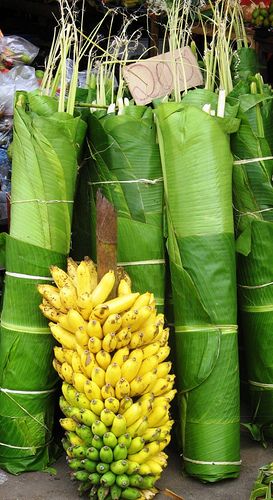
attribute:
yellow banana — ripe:
[101, 329, 119, 352]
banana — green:
[98, 445, 113, 462]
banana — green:
[78, 258, 96, 295]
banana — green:
[88, 270, 117, 305]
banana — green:
[101, 312, 122, 332]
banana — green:
[46, 263, 67, 292]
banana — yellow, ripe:
[128, 333, 142, 348]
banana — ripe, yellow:
[24, 250, 187, 497]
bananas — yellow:
[37, 260, 187, 432]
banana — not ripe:
[71, 424, 145, 489]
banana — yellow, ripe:
[48, 262, 79, 301]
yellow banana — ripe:
[87, 270, 116, 300]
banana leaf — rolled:
[1, 322, 52, 472]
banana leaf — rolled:
[155, 88, 243, 488]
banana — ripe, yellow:
[26, 251, 199, 415]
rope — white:
[192, 458, 227, 465]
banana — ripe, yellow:
[48, 249, 150, 411]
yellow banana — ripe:
[65, 256, 79, 279]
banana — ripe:
[35, 250, 177, 433]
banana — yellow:
[104, 362, 128, 391]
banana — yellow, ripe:
[5, 253, 186, 499]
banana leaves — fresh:
[7, 82, 70, 239]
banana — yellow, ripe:
[93, 286, 142, 317]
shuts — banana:
[43, 7, 252, 108]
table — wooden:
[153, 9, 264, 82]